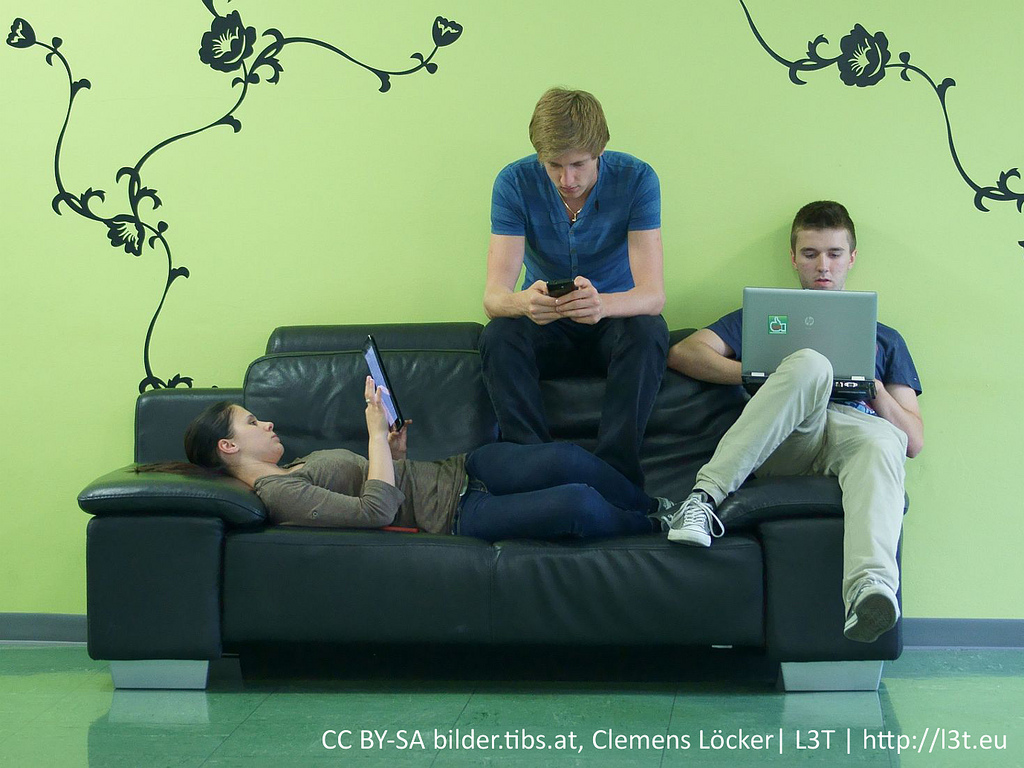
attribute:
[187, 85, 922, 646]
people — young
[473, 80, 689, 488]
person — young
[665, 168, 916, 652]
person — young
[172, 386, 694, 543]
person — young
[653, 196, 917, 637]
man — young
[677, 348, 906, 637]
pants — brown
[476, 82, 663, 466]
man — young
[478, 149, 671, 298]
shirt — blue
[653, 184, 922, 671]
man — young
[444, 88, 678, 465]
man — young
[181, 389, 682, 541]
woman — young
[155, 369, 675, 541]
woman — young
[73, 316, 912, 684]
sofa — black, leather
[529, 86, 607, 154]
hair — brown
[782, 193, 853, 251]
hair — brown, short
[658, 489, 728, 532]
shoelace — white